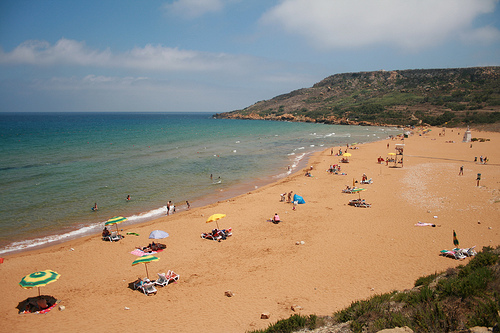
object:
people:
[270, 212, 282, 225]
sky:
[0, 0, 499, 118]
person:
[165, 199, 173, 215]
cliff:
[213, 65, 499, 131]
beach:
[1, 112, 499, 332]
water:
[0, 111, 414, 251]